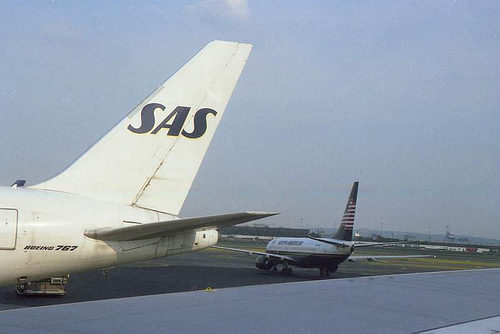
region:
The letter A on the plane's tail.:
[147, 97, 185, 145]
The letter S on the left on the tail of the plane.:
[125, 95, 160, 137]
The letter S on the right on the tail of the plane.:
[189, 99, 214, 141]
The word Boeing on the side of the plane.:
[23, 237, 58, 254]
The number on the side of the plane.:
[55, 238, 80, 256]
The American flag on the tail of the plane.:
[339, 199, 356, 228]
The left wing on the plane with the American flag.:
[212, 238, 294, 266]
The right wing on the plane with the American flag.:
[341, 245, 442, 262]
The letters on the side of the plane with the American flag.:
[276, 237, 310, 248]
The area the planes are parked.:
[0, 221, 496, 315]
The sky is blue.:
[251, 10, 465, 196]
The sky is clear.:
[1, 2, 464, 203]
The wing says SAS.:
[112, 64, 217, 164]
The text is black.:
[111, 57, 226, 156]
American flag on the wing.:
[335, 175, 359, 249]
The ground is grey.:
[32, 270, 492, 332]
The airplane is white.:
[5, 29, 256, 289]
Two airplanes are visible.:
[5, 19, 383, 309]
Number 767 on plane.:
[52, 235, 85, 262]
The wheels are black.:
[272, 257, 342, 280]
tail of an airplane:
[6, 59, 278, 301]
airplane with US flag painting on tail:
[206, 193, 411, 299]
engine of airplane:
[242, 242, 280, 272]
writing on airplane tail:
[130, 89, 225, 150]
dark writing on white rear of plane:
[11, 228, 103, 261]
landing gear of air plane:
[267, 262, 343, 293]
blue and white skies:
[91, 16, 486, 136]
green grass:
[387, 246, 494, 294]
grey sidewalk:
[265, 256, 470, 333]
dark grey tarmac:
[111, 239, 294, 282]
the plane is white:
[1, 17, 252, 320]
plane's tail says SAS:
[125, 75, 220, 165]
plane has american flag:
[250, 162, 375, 332]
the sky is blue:
[0, 0, 471, 152]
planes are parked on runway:
[0, 23, 368, 325]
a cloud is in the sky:
[190, 0, 350, 65]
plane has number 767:
[32, 221, 82, 259]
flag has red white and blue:
[338, 191, 363, 233]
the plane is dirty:
[0, 15, 266, 311]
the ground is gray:
[199, 248, 492, 318]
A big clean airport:
[13, 18, 472, 332]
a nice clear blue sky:
[293, 86, 498, 169]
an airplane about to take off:
[7, 65, 266, 282]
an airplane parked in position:
[218, 179, 431, 279]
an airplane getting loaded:
[6, 255, 82, 300]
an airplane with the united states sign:
[328, 184, 384, 248]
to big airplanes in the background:
[8, 20, 449, 277]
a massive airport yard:
[193, 205, 488, 265]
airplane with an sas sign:
[118, 95, 240, 160]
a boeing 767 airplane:
[23, 230, 222, 282]